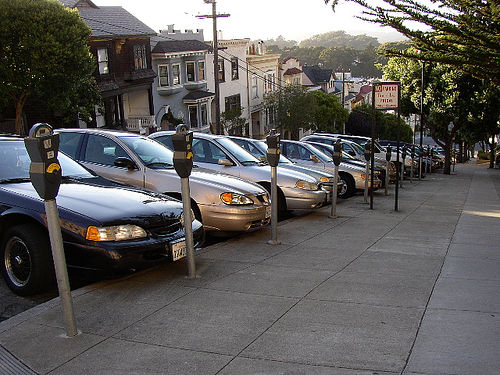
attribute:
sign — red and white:
[376, 85, 399, 113]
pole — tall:
[202, 0, 225, 127]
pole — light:
[183, 6, 253, 137]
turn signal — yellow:
[83, 224, 100, 239]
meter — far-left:
[23, 122, 86, 337]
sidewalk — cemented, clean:
[1, 147, 492, 373]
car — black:
[1, 136, 206, 296]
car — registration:
[8, 131, 239, 305]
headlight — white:
[97, 220, 149, 249]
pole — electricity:
[166, 0, 313, 192]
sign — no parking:
[370, 80, 398, 111]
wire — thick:
[86, 26, 303, 97]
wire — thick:
[75, 14, 295, 86]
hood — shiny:
[7, 178, 182, 228]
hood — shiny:
[163, 166, 263, 196]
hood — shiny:
[260, 164, 317, 187]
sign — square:
[371, 83, 397, 109]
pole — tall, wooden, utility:
[334, 66, 354, 137]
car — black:
[14, 133, 205, 280]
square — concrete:
[111, 285, 302, 357]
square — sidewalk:
[235, 296, 431, 374]